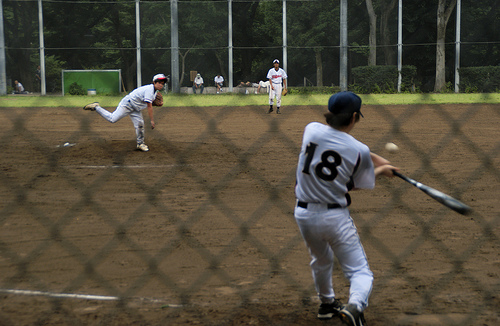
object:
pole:
[169, 0, 181, 96]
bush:
[347, 64, 426, 95]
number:
[301, 141, 319, 176]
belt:
[297, 201, 348, 209]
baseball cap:
[152, 73, 168, 82]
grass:
[0, 92, 500, 109]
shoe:
[316, 299, 345, 320]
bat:
[389, 169, 475, 216]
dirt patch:
[199, 231, 266, 280]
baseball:
[384, 142, 400, 154]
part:
[82, 293, 101, 297]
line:
[0, 288, 188, 308]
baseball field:
[0, 90, 500, 321]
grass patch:
[453, 94, 492, 104]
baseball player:
[293, 90, 399, 326]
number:
[314, 149, 342, 182]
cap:
[327, 90, 364, 118]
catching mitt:
[152, 91, 164, 107]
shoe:
[337, 302, 368, 324]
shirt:
[293, 121, 377, 209]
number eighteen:
[301, 140, 342, 181]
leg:
[82, 101, 129, 124]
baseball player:
[265, 58, 288, 114]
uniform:
[292, 121, 376, 313]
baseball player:
[83, 73, 168, 152]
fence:
[1, 41, 499, 87]